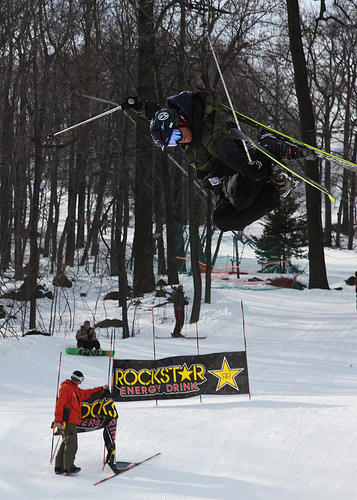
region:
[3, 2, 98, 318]
bare deciduous trees in winter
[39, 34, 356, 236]
skier performing a trick jump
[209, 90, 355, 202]
skier's legs tucked behind him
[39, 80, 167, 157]
ski pole in right hand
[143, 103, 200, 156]
skier's helmet and goggles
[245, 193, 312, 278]
small fir tree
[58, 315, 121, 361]
seated person with green snowboard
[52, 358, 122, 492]
person with red parka fixing a banner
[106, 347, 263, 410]
advertising banner at a skiing event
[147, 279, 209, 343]
person standing on skis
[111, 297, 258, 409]
Rockstar Energy drink banner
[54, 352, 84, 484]
man in red jacket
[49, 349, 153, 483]
Man in ski jacket fixing banner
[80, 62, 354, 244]
Man jumping on skis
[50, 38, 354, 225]
man doing midair trick on skis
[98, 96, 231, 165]
man in helmet and sunglasses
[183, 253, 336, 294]
orange snow fence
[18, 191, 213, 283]
winter forest landscape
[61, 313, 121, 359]
Man on snowboard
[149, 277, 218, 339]
man on skis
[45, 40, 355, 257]
Man skiing and is in midair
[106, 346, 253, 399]
Rockstar energy drink banner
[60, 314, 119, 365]
Man on snowboard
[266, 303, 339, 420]
Snow slope on hill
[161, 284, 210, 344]
Man skiing down the hill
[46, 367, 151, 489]
Man taking down a banner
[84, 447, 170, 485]
Ski pole on ground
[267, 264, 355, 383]
Tracks in snow from skis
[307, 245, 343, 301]
Trunk of tree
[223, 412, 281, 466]
White snow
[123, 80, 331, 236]
a skier jumping in the air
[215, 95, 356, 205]
yellow and black skis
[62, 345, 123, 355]
a green and black snowboard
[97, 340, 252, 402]
a black banner with yellow and pink writing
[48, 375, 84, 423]
a red coat on a man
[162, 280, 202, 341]
a man standing on skis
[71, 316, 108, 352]
a man sitting down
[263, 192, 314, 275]
a green pine tree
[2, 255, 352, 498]
a white snowy slope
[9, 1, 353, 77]
a cloudy blue sky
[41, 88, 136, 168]
A skiing pole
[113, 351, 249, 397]
Advertising banner for Rockstar Energy Drinks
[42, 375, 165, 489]
A man holding a folded advertising banner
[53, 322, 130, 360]
A snowboarder sitting down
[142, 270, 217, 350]
A skier standing up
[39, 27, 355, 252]
A skier in mid air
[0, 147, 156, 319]
A snowy forest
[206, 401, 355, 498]
A field of snow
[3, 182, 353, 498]
A recreational skiing course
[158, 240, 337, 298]
A blocked off area